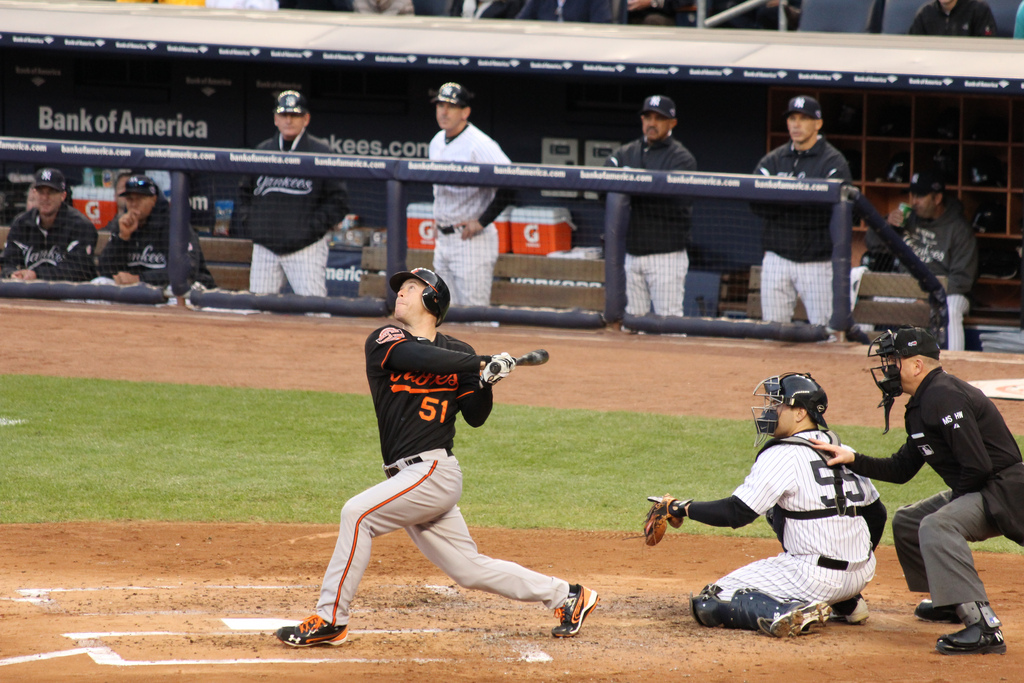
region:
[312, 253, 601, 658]
Batter looking skyward after hitting the ball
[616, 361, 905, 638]
Catcher squatting on the diamond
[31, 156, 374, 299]
Baseball players watching from the dugout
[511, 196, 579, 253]
Orange cooler with a capital G on it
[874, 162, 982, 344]
Man sitting and having a drink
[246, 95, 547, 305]
Baseball players standing in the dugout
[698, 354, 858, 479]
Baseball player wearing catcher's helmet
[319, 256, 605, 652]
Baseball player wearing a hitting helmet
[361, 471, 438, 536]
stripe is on the pants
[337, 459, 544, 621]
the pants are gray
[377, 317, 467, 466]
the shirt is black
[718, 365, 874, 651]
the man is in the dirt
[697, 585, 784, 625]
knee guard is black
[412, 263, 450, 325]
the helmet is black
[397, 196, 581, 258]
the coolers are orange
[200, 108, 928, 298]
men in the dug out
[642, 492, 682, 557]
baseball glove is on the hand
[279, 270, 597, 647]
man swinging a bat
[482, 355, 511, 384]
the gloves are white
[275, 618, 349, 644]
black and orange shoe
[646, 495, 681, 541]
the glove is brown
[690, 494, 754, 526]
the sleeve is black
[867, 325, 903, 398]
the mask is black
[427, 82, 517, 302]
man watching the game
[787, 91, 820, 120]
the hat is black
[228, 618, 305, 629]
the base is white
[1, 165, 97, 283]
baseball player sitting in dugout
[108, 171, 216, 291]
baseball player sitting in dugout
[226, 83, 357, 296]
baseball player standing in dugout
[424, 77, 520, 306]
baseball player standing in dugout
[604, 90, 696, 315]
baseball player standing in dugout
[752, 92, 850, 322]
baseball player standing in dugout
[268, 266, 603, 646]
baseball player holding black bat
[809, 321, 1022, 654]
umpire standing behind catcher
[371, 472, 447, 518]
the stripe is orange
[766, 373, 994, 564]
man is touching the catcher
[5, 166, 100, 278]
A person sitting down.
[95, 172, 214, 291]
A person sitting down.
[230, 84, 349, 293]
A person is standing up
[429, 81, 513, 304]
A person is standing up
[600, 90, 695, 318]
A person is standing up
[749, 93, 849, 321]
A person is standing up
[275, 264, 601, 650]
A person is swinging a baseball bat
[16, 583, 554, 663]
A box on the ground for batters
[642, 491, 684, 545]
A glove used for baseball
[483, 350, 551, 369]
The bat in the batter's hands.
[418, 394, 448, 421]
The number 51 on the batter's uniform shirt.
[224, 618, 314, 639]
The home plate in front of the batter.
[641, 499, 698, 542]
The glove on the catcher's hand.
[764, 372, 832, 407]
The helmet the catcher is wearing.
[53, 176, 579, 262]
The orange and white coolers in the dug out.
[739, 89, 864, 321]
A person is standing up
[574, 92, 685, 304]
A person is standing up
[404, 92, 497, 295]
A person is standing up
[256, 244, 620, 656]
A baseball player holding a bat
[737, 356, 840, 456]
A catcher wearing a helmet and face mask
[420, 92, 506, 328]
A person is standing up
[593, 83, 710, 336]
A person is standing up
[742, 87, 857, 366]
A person is standing up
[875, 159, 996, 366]
A person is standing up